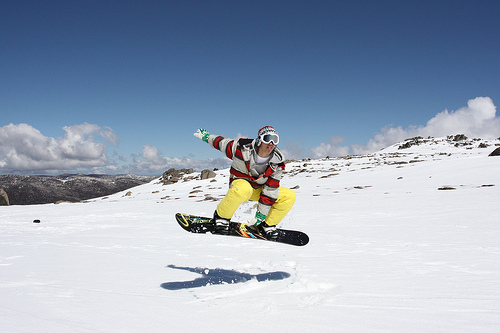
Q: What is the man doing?
A: Snowboarding.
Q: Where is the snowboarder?
A: In the air.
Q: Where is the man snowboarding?
A: On a mountain.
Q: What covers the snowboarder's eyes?
A: Goggles.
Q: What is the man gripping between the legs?
A: Snowboard.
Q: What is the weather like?
A: Mostly clear.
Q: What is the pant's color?
A: Yellow.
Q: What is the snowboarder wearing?
A: Striped sweater.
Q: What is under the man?
A: A snowboard.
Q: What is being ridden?
A: Snowboard.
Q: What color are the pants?
A: Yellow.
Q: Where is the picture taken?
A: On a mountain.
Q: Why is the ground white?
A: It is snow.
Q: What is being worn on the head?
A: Hat.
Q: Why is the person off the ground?
A: Jumping.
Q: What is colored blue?
A: Sky.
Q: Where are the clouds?
A: Sky.